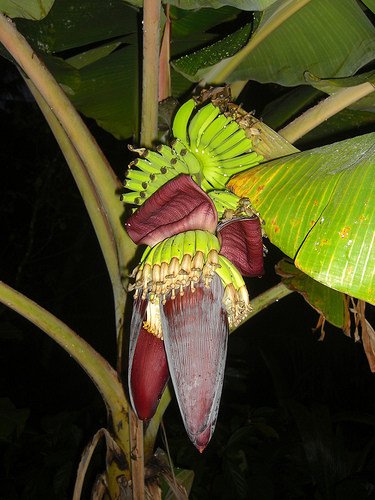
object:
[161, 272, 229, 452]
bulb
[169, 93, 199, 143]
fruit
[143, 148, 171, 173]
bananas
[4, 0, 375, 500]
tree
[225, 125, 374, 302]
leaves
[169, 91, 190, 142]
banana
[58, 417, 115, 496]
leaves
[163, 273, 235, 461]
flowery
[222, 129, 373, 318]
leaf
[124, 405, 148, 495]
stalk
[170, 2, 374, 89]
leaf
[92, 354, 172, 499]
trunk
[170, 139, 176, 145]
black tip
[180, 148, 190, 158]
tip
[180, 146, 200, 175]
banana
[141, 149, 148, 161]
black tip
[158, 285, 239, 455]
plant pod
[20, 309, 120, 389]
leaf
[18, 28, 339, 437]
sentence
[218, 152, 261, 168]
banana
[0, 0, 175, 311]
branches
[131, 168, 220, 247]
petal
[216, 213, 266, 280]
petal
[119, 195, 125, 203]
tip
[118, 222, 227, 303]
bunch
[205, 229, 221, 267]
banana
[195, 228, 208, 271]
banana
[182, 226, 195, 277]
banana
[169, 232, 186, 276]
banana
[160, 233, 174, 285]
banana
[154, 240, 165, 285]
banana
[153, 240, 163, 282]
banana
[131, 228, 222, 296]
banana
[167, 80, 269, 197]
bunch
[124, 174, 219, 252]
plant pod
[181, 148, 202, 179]
bananas